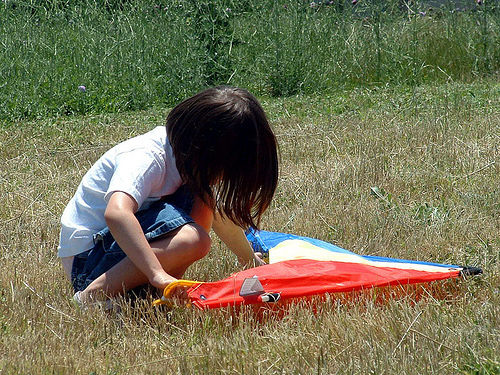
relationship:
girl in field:
[59, 84, 283, 318] [0, 76, 497, 373]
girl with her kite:
[59, 84, 283, 318] [154, 222, 493, 307]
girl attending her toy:
[59, 84, 283, 318] [174, 220, 483, 315]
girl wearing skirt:
[59, 84, 283, 318] [69, 181, 221, 293]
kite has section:
[151, 226, 483, 310] [242, 221, 462, 272]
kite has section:
[176, 220, 486, 312] [187, 256, 464, 308]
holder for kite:
[152, 269, 213, 307] [185, 222, 482, 308]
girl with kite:
[59, 84, 283, 318] [155, 221, 488, 318]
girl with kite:
[62, 89, 285, 294] [167, 223, 477, 310]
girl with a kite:
[59, 84, 283, 318] [176, 220, 486, 312]